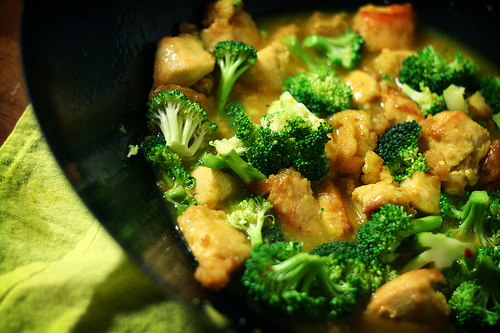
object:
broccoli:
[396, 45, 491, 99]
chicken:
[347, 1, 415, 54]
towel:
[0, 101, 193, 332]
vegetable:
[225, 194, 277, 249]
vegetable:
[145, 86, 220, 166]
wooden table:
[0, 0, 30, 148]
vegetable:
[433, 190, 499, 252]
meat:
[363, 268, 453, 332]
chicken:
[254, 166, 322, 238]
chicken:
[173, 204, 255, 290]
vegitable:
[446, 280, 499, 326]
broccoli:
[239, 239, 367, 322]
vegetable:
[206, 40, 257, 116]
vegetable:
[370, 119, 429, 184]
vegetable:
[352, 199, 446, 273]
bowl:
[16, 0, 499, 332]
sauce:
[146, 16, 499, 332]